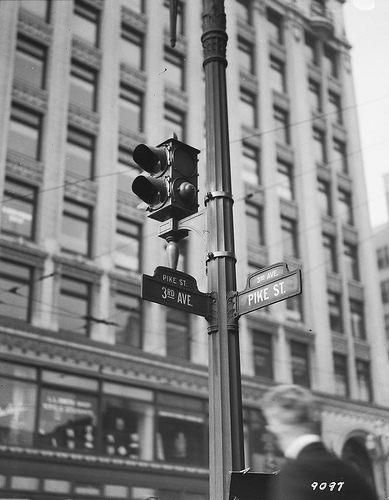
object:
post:
[201, 3, 248, 499]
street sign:
[139, 265, 208, 319]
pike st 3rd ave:
[160, 271, 193, 309]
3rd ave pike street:
[243, 266, 287, 309]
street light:
[131, 129, 202, 238]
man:
[256, 382, 378, 499]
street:
[1, 480, 387, 500]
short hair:
[256, 382, 321, 434]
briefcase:
[228, 469, 280, 499]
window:
[267, 9, 285, 48]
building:
[1, 2, 388, 496]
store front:
[3, 355, 213, 472]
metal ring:
[202, 189, 236, 206]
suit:
[269, 436, 380, 498]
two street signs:
[232, 259, 304, 326]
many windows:
[54, 267, 94, 339]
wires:
[1, 90, 389, 205]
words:
[27, 211, 33, 221]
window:
[2, 179, 40, 242]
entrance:
[337, 426, 388, 497]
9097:
[309, 480, 343, 492]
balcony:
[307, 0, 337, 34]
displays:
[3, 382, 32, 444]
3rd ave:
[253, 270, 280, 284]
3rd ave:
[161, 285, 195, 309]